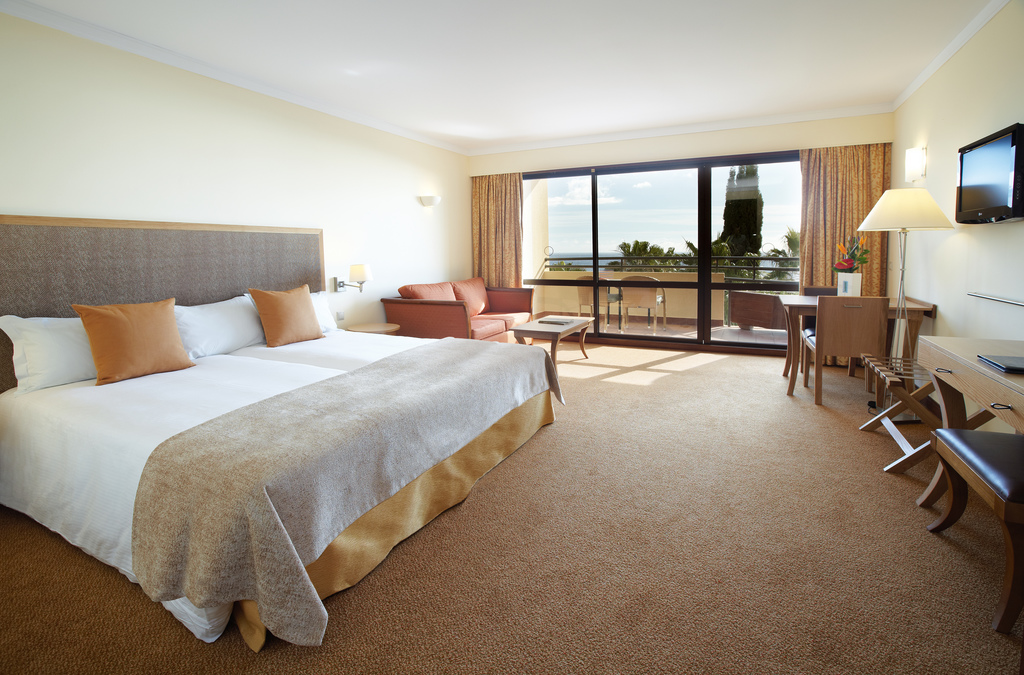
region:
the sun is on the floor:
[542, 317, 724, 407]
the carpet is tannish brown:
[547, 355, 849, 597]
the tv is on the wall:
[911, 89, 1016, 235]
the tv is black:
[927, 106, 1020, 247]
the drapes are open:
[431, 96, 935, 302]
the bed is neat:
[43, 239, 546, 528]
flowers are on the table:
[808, 178, 884, 316]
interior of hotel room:
[3, 2, 1021, 673]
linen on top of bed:
[0, 287, 566, 655]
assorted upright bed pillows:
[5, 282, 338, 387]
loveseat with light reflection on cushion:
[386, 279, 535, 336]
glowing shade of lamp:
[860, 189, 952, 304]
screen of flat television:
[951, 123, 1022, 225]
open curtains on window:
[473, 142, 888, 358]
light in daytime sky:
[519, 162, 804, 276]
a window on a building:
[515, 177, 592, 277]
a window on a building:
[522, 282, 600, 324]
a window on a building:
[594, 168, 697, 289]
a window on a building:
[711, 156, 797, 290]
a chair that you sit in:
[907, 404, 1015, 581]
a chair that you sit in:
[792, 279, 894, 398]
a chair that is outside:
[609, 265, 679, 329]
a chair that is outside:
[577, 262, 629, 336]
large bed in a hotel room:
[2, 211, 568, 654]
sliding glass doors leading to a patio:
[468, 141, 898, 357]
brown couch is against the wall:
[379, 274, 535, 341]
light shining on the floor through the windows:
[525, 337, 731, 389]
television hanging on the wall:
[954, 121, 1022, 229]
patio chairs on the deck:
[574, 272, 672, 333]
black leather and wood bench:
[926, 423, 1022, 635]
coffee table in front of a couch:
[508, 313, 598, 367]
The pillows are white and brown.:
[0, 279, 340, 385]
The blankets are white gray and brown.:
[15, 325, 566, 629]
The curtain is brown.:
[473, 171, 532, 288]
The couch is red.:
[376, 265, 533, 330]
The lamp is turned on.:
[853, 177, 953, 351]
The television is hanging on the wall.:
[951, 124, 1022, 229]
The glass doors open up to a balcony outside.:
[520, 158, 818, 367]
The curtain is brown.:
[800, 143, 889, 293]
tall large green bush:
[723, 166, 765, 275]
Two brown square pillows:
[68, 269, 328, 394]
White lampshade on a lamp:
[841, 171, 962, 318]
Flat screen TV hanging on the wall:
[943, 109, 1016, 233]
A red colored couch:
[371, 267, 545, 351]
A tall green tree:
[712, 152, 767, 292]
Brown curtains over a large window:
[459, 128, 894, 357]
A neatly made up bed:
[0, 200, 580, 656]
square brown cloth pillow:
[69, 296, 203, 388]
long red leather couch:
[381, 276, 538, 346]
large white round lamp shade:
[853, 186, 965, 234]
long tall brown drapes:
[463, 170, 525, 284]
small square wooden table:
[513, 309, 596, 371]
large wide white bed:
[1, 213, 568, 650]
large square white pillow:
[1, 314, 100, 390]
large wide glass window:
[520, 153, 802, 344]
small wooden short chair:
[798, 296, 893, 402]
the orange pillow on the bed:
[81, 294, 196, 378]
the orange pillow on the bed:
[247, 284, 321, 338]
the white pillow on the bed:
[4, 304, 103, 390]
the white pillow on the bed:
[166, 287, 271, 351]